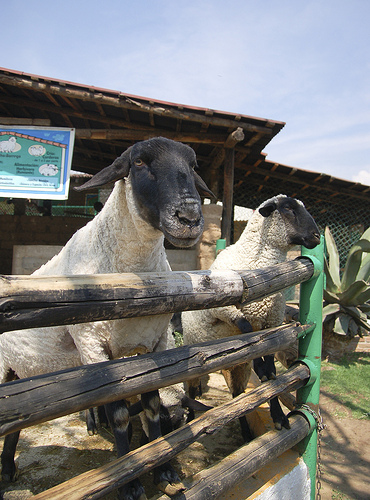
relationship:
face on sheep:
[119, 139, 214, 245] [14, 151, 194, 457]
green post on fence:
[297, 230, 326, 498] [3, 251, 313, 497]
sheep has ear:
[0, 136, 218, 500] [76, 156, 132, 197]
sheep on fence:
[3, 126, 225, 385] [0, 255, 315, 500]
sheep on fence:
[182, 194, 320, 443] [0, 255, 315, 500]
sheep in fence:
[0, 136, 218, 500] [0, 239, 323, 462]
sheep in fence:
[189, 193, 325, 435] [0, 239, 323, 462]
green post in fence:
[296, 233, 325, 498] [0, 234, 324, 497]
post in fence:
[214, 236, 225, 253] [0, 234, 324, 497]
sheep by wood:
[0, 136, 218, 500] [65, 353, 228, 461]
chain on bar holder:
[294, 402, 327, 500] [82, 255, 352, 473]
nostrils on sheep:
[172, 206, 201, 226] [181, 195, 322, 430]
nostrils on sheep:
[313, 231, 320, 241] [0, 136, 218, 500]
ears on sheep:
[74, 165, 220, 197] [0, 136, 218, 500]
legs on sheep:
[72, 351, 180, 497] [3, 133, 202, 496]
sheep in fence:
[0, 136, 218, 500] [60, 228, 361, 383]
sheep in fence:
[1, 134, 321, 483] [0, 255, 315, 500]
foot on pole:
[154, 465, 188, 497] [153, 402, 309, 498]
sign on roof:
[1, 122, 74, 202] [2, 66, 289, 126]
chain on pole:
[298, 398, 326, 498] [295, 227, 323, 493]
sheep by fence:
[0, 136, 218, 500] [320, 245, 365, 493]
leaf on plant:
[340, 240, 369, 291] [323, 225, 368, 336]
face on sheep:
[126, 130, 204, 233] [97, 144, 202, 332]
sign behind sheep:
[0, 124, 76, 200] [67, 116, 224, 301]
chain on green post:
[294, 402, 327, 500] [296, 233, 325, 498]